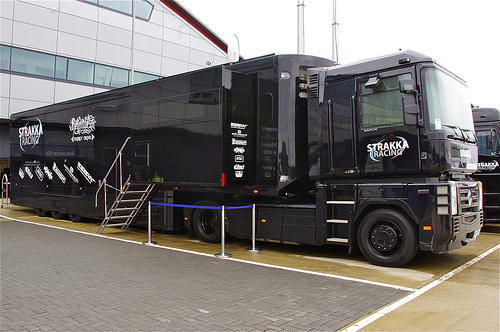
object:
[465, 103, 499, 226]
truck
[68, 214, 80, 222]
tire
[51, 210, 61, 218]
tire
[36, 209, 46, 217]
tire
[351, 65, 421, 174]
door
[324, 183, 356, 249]
steps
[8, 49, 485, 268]
camper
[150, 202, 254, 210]
rope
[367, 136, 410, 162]
logo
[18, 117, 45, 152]
logo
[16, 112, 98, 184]
sponsors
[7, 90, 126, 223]
backend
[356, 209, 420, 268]
right tire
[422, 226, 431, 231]
light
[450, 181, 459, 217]
headlight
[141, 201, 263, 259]
barricade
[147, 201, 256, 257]
rods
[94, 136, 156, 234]
stairs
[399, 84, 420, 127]
side-view mirror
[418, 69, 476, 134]
windshield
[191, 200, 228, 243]
side wheel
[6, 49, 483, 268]
truck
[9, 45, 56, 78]
window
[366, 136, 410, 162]
letter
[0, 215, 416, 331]
sidewalk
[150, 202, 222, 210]
cord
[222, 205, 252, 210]
cord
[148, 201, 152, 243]
pole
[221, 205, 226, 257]
pole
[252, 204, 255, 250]
pole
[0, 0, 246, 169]
building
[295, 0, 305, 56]
pole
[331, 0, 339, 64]
pole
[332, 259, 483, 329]
line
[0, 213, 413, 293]
line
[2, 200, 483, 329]
lot